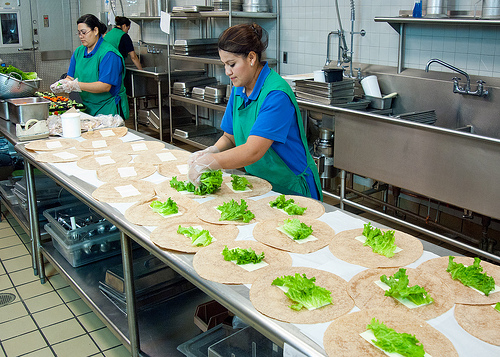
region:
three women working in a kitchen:
[72, 10, 350, 242]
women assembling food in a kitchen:
[48, 18, 453, 350]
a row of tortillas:
[18, 108, 462, 352]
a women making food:
[167, 17, 354, 213]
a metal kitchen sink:
[329, 41, 497, 208]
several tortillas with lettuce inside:
[135, 159, 465, 352]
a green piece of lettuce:
[276, 269, 328, 310]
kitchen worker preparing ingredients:
[21, 10, 160, 136]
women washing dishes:
[102, 8, 226, 134]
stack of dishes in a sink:
[289, 14, 445, 156]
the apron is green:
[213, 74, 355, 254]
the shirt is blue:
[186, 64, 323, 184]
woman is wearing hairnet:
[205, 7, 303, 85]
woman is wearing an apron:
[168, 39, 314, 193]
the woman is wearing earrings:
[203, 16, 282, 111]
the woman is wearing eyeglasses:
[63, 19, 120, 58]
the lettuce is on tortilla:
[143, 122, 383, 326]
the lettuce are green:
[154, 129, 293, 261]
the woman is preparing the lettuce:
[158, 30, 370, 273]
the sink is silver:
[331, 55, 493, 243]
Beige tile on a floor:
[7, 291, 94, 354]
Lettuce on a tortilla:
[249, 265, 327, 325]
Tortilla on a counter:
[190, 239, 289, 281]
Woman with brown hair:
[208, 20, 350, 203]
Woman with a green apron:
[200, 26, 306, 195]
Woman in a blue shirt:
[203, 38, 315, 185]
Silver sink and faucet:
[346, 53, 493, 168]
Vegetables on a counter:
[26, 76, 99, 130]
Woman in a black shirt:
[91, 9, 153, 70]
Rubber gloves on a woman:
[166, 137, 246, 197]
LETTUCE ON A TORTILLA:
[276, 213, 322, 245]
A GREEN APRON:
[222, 86, 344, 213]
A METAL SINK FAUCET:
[419, 51, 499, 105]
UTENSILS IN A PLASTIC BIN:
[40, 200, 130, 270]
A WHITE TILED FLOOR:
[11, 284, 94, 355]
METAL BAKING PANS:
[159, 74, 236, 110]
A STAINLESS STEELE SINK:
[329, 61, 496, 215]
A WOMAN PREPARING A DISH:
[173, 21, 322, 192]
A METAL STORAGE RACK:
[151, 7, 305, 169]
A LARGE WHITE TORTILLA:
[242, 263, 355, 325]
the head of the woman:
[215, 13, 271, 91]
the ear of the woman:
[241, 46, 256, 71]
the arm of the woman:
[180, 81, 300, 176]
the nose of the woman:
[220, 57, 231, 77]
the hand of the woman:
[182, 147, 217, 182]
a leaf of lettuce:
[270, 270, 336, 312]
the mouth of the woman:
[225, 70, 235, 85]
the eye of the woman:
[226, 55, 237, 66]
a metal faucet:
[416, 48, 490, 103]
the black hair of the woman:
[76, 11, 111, 34]